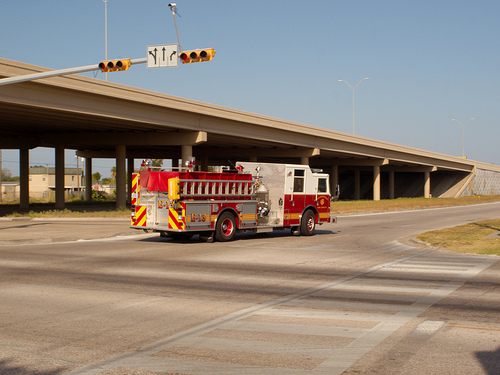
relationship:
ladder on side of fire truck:
[167, 177, 256, 201] [126, 154, 343, 244]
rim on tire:
[219, 220, 240, 241] [215, 211, 236, 242]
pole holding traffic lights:
[18, 50, 170, 90] [92, 37, 223, 63]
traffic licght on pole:
[174, 47, 216, 64] [0, 55, 147, 88]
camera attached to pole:
[163, 0, 193, 47] [6, 41, 221, 108]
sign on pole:
[144, 45, 178, 68] [0, 39, 218, 115]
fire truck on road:
[128, 157, 341, 243] [7, 236, 496, 368]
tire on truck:
[215, 210, 235, 243] [131, 159, 334, 241]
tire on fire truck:
[296, 206, 316, 235] [126, 154, 343, 244]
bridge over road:
[0, 53, 499, 212] [24, 196, 476, 372]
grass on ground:
[405, 193, 499, 288] [40, 199, 480, 360]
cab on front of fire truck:
[250, 161, 334, 224] [106, 146, 345, 247]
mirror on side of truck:
[331, 178, 338, 199] [122, 160, 336, 251]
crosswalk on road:
[65, 257, 499, 371] [345, 203, 497, 291]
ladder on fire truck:
[168, 175, 259, 202] [126, 154, 343, 244]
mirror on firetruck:
[335, 184, 341, 199] [125, 152, 337, 245]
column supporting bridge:
[18, 148, 30, 207] [1, 53, 493, 208]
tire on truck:
[301, 208, 315, 237] [157, 156, 330, 228]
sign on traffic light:
[144, 45, 178, 68] [103, 40, 270, 88]